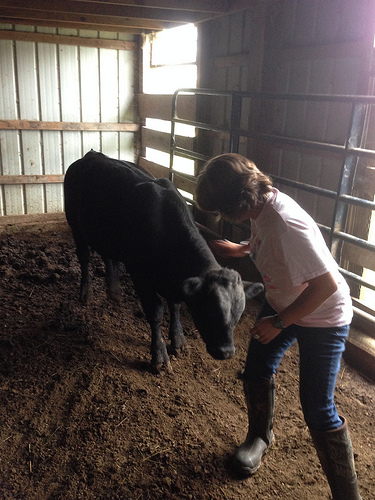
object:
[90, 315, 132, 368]
dirt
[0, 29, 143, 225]
slats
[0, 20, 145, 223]
wall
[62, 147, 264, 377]
cow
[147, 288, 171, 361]
leg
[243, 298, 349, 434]
jeans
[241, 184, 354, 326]
shirt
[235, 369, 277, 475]
boot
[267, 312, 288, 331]
watch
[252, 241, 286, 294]
design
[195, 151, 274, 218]
hair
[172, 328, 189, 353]
hoof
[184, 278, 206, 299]
ear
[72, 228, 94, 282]
legs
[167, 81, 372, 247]
guard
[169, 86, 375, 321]
bars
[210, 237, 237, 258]
hand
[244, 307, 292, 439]
leg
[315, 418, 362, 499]
boot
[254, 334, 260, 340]
ring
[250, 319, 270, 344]
woman's finger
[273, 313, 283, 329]
clock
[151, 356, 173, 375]
hoof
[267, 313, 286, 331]
wrist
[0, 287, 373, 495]
farm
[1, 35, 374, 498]
barn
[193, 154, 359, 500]
lady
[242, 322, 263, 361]
finger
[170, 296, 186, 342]
legs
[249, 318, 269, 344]
finger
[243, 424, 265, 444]
gap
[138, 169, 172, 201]
hump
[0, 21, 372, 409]
pen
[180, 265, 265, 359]
head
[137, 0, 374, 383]
wall